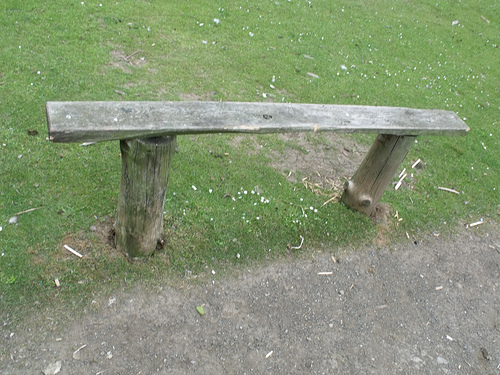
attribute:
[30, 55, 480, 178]
bench — wooden, park, wood, holding, stumps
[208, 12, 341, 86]
grass — patch, green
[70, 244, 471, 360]
path — walking, gravel, pavement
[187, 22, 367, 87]
debris — random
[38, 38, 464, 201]
plank — wooden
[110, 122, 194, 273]
stump — tree, bench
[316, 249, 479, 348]
trail — hiking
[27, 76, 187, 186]
log — on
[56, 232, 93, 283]
trash — laying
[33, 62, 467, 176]
board — weathered, thin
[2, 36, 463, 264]
tablet — wooden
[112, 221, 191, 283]
wood — splinter